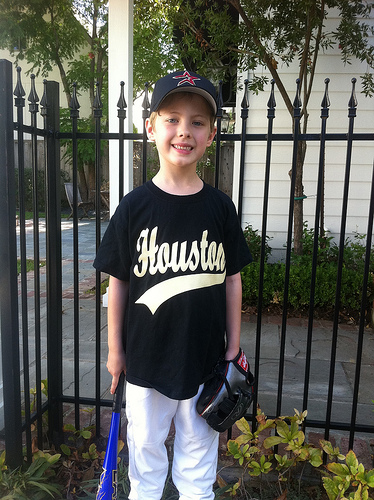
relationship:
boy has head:
[93, 71, 247, 498] [146, 67, 219, 166]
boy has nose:
[93, 71, 247, 498] [178, 124, 192, 139]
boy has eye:
[93, 71, 247, 498] [192, 121, 206, 128]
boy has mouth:
[93, 71, 247, 498] [170, 145, 195, 155]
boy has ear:
[93, 71, 247, 498] [143, 116, 154, 142]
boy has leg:
[93, 71, 247, 498] [125, 384, 170, 500]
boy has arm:
[93, 71, 247, 498] [218, 196, 243, 359]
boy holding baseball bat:
[93, 71, 247, 498] [95, 373, 124, 500]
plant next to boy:
[215, 406, 373, 499] [93, 71, 247, 498]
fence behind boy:
[1, 62, 373, 471] [93, 71, 247, 498]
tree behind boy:
[168, 1, 373, 255] [93, 71, 247, 498]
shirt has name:
[94, 178, 251, 398] [133, 229, 226, 314]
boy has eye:
[93, 71, 247, 498] [168, 119, 179, 125]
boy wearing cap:
[93, 71, 247, 498] [149, 69, 222, 124]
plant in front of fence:
[215, 406, 373, 499] [1, 62, 373, 471]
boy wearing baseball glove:
[93, 71, 247, 498] [194, 347, 252, 431]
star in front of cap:
[174, 69, 199, 88] [149, 69, 222, 124]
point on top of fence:
[242, 78, 250, 110] [1, 62, 373, 471]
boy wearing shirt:
[93, 71, 247, 498] [94, 178, 251, 398]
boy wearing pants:
[93, 71, 247, 498] [126, 379, 219, 499]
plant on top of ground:
[215, 406, 373, 499] [0, 218, 373, 500]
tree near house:
[168, 1, 373, 255] [107, 0, 373, 266]